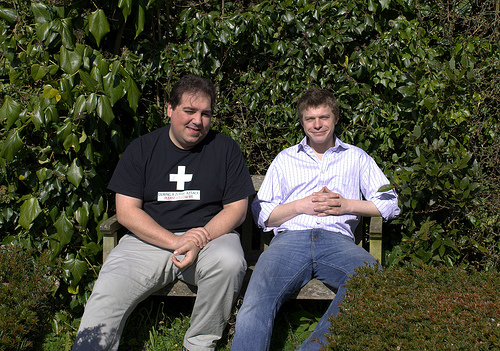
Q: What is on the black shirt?
A: Cross.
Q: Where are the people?
A: Sitting on a bench.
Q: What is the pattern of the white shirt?
A: Stripes.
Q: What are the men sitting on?
A: Bench.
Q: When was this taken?
A: Daytime.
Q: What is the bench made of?
A: Wood.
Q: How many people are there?
A: 2.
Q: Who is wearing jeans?
A: The man on the right.